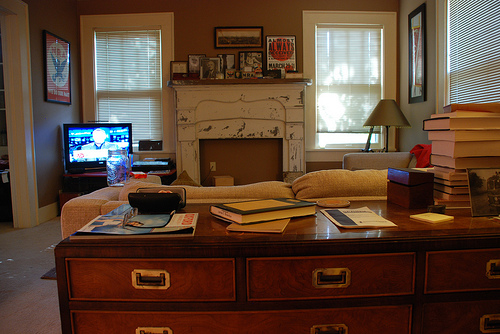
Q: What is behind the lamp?
A: A window with blinds.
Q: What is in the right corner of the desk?
A: A pile of books.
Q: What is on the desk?
A: A box.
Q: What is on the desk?
A: Pile of books.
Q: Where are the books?
A: On the desk.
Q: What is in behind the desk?
A: A couch.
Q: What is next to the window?
A: A fireplace.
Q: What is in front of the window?
A: A tv screen.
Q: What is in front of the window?
A: A lamp.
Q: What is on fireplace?
A: Pictures.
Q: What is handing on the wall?
A: A poster.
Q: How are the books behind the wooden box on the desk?
A: Stacked.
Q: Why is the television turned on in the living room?
A: To watch.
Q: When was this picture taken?
A: Daytime.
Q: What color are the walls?
A: Brown.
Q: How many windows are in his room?
A: 3.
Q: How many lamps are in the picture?
A: 1.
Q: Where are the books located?
A: Desk.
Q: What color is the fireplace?
A: White.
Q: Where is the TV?
A: Left corner.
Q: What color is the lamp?
A: Green.